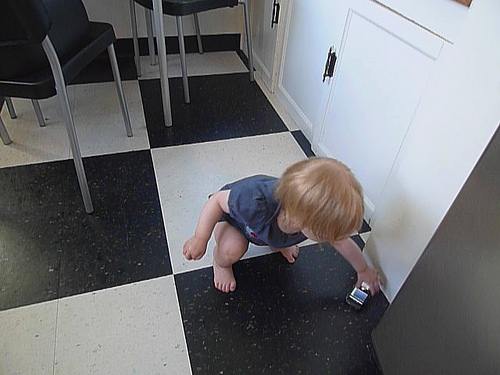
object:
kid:
[183, 154, 383, 296]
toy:
[342, 273, 374, 315]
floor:
[108, 157, 180, 367]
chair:
[0, 0, 135, 213]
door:
[310, 0, 453, 224]